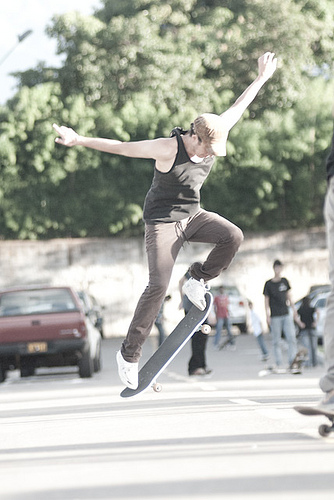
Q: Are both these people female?
A: No, they are both male and female.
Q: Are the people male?
A: No, they are both male and female.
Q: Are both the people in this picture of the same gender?
A: No, they are both male and female.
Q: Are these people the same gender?
A: No, they are both male and female.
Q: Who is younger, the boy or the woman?
A: The boy is younger than the woman.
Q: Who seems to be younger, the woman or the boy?
A: The boy is younger than the woman.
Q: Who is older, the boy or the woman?
A: The woman is older than the boy.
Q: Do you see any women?
A: Yes, there is a woman.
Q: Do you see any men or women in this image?
A: Yes, there is a woman.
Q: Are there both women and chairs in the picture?
A: No, there is a woman but no chairs.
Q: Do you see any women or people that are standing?
A: Yes, the woman is standing.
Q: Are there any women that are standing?
A: Yes, there is a woman that is standing.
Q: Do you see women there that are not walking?
A: Yes, there is a woman that is standing .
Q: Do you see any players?
A: No, there are no players.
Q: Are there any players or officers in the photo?
A: No, there are no players or officers.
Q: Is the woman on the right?
A: Yes, the woman is on the right of the image.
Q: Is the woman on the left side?
A: No, the woman is on the right of the image.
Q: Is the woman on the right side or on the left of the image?
A: The woman is on the right of the image.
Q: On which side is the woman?
A: The woman is on the right of the image.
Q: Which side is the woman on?
A: The woman is on the right of the image.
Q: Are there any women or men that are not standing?
A: No, there is a woman but she is standing.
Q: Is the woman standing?
A: Yes, the woman is standing.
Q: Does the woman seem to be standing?
A: Yes, the woman is standing.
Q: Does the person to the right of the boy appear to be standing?
A: Yes, the woman is standing.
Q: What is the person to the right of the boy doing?
A: The woman is standing.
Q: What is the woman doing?
A: The woman is standing.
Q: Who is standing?
A: The woman is standing.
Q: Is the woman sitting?
A: No, the woman is standing.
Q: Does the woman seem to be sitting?
A: No, the woman is standing.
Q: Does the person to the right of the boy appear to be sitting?
A: No, the woman is standing.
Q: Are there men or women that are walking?
A: No, there is a woman but she is standing.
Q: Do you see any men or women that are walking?
A: No, there is a woman but she is standing.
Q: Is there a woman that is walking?
A: No, there is a woman but she is standing.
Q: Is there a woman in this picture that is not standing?
A: No, there is a woman but she is standing.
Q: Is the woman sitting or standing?
A: The woman is standing.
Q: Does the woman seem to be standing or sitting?
A: The woman is standing.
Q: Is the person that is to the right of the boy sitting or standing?
A: The woman is standing.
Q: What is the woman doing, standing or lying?
A: The woman is standing.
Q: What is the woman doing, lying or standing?
A: The woman is standing.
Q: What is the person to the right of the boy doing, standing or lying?
A: The woman is standing.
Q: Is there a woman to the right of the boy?
A: Yes, there is a woman to the right of the boy.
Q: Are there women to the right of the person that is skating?
A: Yes, there is a woman to the right of the boy.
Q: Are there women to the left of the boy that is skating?
A: No, the woman is to the right of the boy.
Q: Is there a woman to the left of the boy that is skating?
A: No, the woman is to the right of the boy.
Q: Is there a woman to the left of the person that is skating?
A: No, the woman is to the right of the boy.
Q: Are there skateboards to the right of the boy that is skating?
A: No, there is a woman to the right of the boy.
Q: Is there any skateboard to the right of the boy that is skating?
A: No, there is a woman to the right of the boy.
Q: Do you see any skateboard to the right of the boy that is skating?
A: No, there is a woman to the right of the boy.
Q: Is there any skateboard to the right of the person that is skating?
A: No, there is a woman to the right of the boy.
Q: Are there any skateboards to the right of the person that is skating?
A: No, there is a woman to the right of the boy.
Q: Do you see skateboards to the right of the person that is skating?
A: No, there is a woman to the right of the boy.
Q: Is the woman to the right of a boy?
A: Yes, the woman is to the right of a boy.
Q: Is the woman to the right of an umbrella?
A: No, the woman is to the right of a boy.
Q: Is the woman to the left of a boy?
A: No, the woman is to the right of a boy.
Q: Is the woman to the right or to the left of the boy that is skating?
A: The woman is to the right of the boy.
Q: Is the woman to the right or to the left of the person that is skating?
A: The woman is to the right of the boy.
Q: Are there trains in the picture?
A: No, there are no trains.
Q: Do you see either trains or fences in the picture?
A: No, there are no trains or fences.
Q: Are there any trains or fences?
A: No, there are no trains or fences.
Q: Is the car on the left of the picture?
A: Yes, the car is on the left of the image.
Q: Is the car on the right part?
A: No, the car is on the left of the image.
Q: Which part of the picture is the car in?
A: The car is on the left of the image.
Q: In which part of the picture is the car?
A: The car is on the left of the image.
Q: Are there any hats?
A: Yes, there is a hat.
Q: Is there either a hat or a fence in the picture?
A: Yes, there is a hat.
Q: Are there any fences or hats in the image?
A: Yes, there is a hat.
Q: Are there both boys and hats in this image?
A: Yes, there are both a hat and a boy.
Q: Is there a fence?
A: No, there are no fences.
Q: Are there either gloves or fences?
A: No, there are no fences or gloves.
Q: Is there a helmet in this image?
A: No, there are no helmets.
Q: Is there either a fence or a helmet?
A: No, there are no helmets or fences.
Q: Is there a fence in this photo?
A: No, there are no fences.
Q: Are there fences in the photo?
A: No, there are no fences.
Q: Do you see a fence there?
A: No, there are no fences.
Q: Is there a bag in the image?
A: No, there are no bags.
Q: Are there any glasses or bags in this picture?
A: No, there are no bags or glasses.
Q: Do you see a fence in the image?
A: No, there are no fences.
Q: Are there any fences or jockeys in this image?
A: No, there are no fences or jockeys.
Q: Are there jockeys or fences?
A: No, there are no fences or jockeys.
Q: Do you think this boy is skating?
A: Yes, the boy is skating.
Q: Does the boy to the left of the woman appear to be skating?
A: Yes, the boy is skating.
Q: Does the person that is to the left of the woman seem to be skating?
A: Yes, the boy is skating.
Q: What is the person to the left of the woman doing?
A: The boy is skating.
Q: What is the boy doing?
A: The boy is skating.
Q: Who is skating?
A: The boy is skating.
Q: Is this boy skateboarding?
A: No, the boy is skating.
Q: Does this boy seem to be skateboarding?
A: No, the boy is skating.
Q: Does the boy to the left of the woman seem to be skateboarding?
A: No, the boy is skating.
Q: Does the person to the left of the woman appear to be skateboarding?
A: No, the boy is skating.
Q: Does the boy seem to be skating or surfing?
A: The boy is skating.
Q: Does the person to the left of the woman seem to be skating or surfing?
A: The boy is skating.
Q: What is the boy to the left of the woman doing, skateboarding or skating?
A: The boy is skating.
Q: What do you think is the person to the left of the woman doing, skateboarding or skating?
A: The boy is skating.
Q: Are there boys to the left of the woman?
A: Yes, there is a boy to the left of the woman.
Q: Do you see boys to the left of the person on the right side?
A: Yes, there is a boy to the left of the woman.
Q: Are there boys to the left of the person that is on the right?
A: Yes, there is a boy to the left of the woman.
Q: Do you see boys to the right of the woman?
A: No, the boy is to the left of the woman.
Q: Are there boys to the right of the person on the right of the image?
A: No, the boy is to the left of the woman.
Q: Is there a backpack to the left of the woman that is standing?
A: No, there is a boy to the left of the woman.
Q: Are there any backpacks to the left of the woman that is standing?
A: No, there is a boy to the left of the woman.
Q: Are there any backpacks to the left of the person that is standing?
A: No, there is a boy to the left of the woman.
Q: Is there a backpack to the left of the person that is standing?
A: No, there is a boy to the left of the woman.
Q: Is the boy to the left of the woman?
A: Yes, the boy is to the left of the woman.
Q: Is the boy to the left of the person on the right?
A: Yes, the boy is to the left of the woman.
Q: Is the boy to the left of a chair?
A: No, the boy is to the left of the woman.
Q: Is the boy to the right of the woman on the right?
A: No, the boy is to the left of the woman.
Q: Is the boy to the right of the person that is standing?
A: No, the boy is to the left of the woman.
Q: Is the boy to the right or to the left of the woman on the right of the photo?
A: The boy is to the left of the woman.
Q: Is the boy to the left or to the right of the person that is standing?
A: The boy is to the left of the woman.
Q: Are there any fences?
A: No, there are no fences.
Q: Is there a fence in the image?
A: No, there are no fences.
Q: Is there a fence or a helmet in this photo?
A: No, there are no fences or helmets.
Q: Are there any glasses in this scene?
A: No, there are no glasses.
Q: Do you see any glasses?
A: No, there are no glasses.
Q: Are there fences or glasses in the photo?
A: No, there are no glasses or fences.